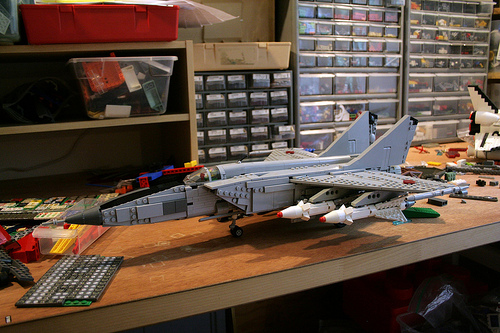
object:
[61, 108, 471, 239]
plane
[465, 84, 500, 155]
tail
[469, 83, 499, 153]
airplane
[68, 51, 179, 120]
box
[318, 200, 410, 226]
missle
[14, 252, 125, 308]
lego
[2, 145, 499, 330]
table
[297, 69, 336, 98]
bin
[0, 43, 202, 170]
shelf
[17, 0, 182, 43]
container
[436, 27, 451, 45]
drawer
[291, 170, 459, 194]
wing